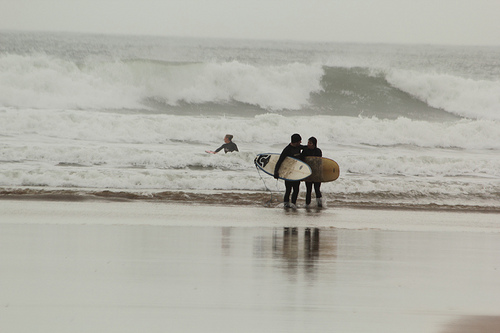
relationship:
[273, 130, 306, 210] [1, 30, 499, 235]
surfer leaving ocean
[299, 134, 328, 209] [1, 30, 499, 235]
surfer leaving ocean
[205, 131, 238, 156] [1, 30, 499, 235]
surfer paddling in ocean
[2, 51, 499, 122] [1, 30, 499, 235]
wave breaking in ocean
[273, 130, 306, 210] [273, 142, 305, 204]
surfer wearing wetsuit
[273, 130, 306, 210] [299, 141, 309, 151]
surfer walking with arm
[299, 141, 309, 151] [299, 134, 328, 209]
arm around surfer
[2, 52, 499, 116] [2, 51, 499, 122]
foam on top of wave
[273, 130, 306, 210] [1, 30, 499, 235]
surfer in ocean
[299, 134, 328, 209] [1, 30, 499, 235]
surfer in ocean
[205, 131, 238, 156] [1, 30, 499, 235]
surfer in ocean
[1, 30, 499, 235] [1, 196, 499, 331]
ocean meeting shore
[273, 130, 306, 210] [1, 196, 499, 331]
surfer standing on shore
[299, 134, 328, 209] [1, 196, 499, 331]
surfer standing on shore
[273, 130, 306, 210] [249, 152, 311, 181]
surfer holding surfboard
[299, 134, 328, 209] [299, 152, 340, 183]
surfer holding surfboard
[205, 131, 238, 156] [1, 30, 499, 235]
surfer swimming in ocean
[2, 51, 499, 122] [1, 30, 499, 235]
wave in ocean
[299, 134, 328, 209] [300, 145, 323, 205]
surfer wearing wetsuit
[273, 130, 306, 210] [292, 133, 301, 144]
surfer wearing hat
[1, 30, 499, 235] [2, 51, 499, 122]
ocean has wave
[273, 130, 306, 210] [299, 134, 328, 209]
surfer next to surfer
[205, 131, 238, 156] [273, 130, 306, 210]
surfer behind surfer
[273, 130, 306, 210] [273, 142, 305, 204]
surfer has wetsuit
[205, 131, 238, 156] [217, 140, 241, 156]
surfer wearing wetsuit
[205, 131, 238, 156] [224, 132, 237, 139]
surfer has hair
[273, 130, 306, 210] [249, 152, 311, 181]
surfer has surfboard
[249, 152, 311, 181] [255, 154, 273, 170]
surfboard has design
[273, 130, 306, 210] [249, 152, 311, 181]
surfer carrying surfboard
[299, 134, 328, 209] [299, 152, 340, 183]
surfer carrying surfboard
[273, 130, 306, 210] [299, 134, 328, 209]
surfer walking with surfer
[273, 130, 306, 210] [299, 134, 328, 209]
surfer with surfer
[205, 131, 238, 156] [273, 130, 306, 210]
surfer with surfer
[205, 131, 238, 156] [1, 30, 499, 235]
surfer out in ocean